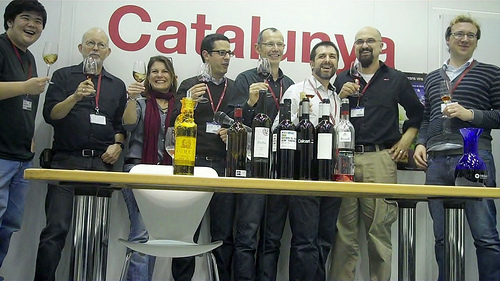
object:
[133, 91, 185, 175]
part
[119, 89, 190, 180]
sweater